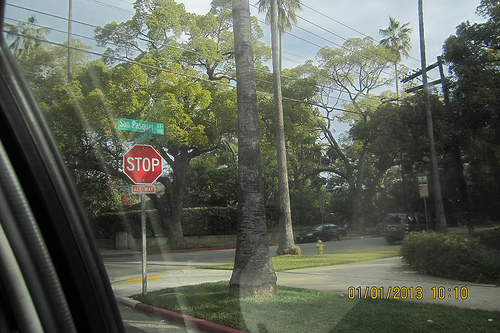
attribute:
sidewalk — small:
[273, 259, 497, 300]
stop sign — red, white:
[121, 141, 163, 196]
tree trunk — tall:
[230, 0, 277, 300]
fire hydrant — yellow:
[312, 237, 327, 254]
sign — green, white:
[116, 117, 165, 134]